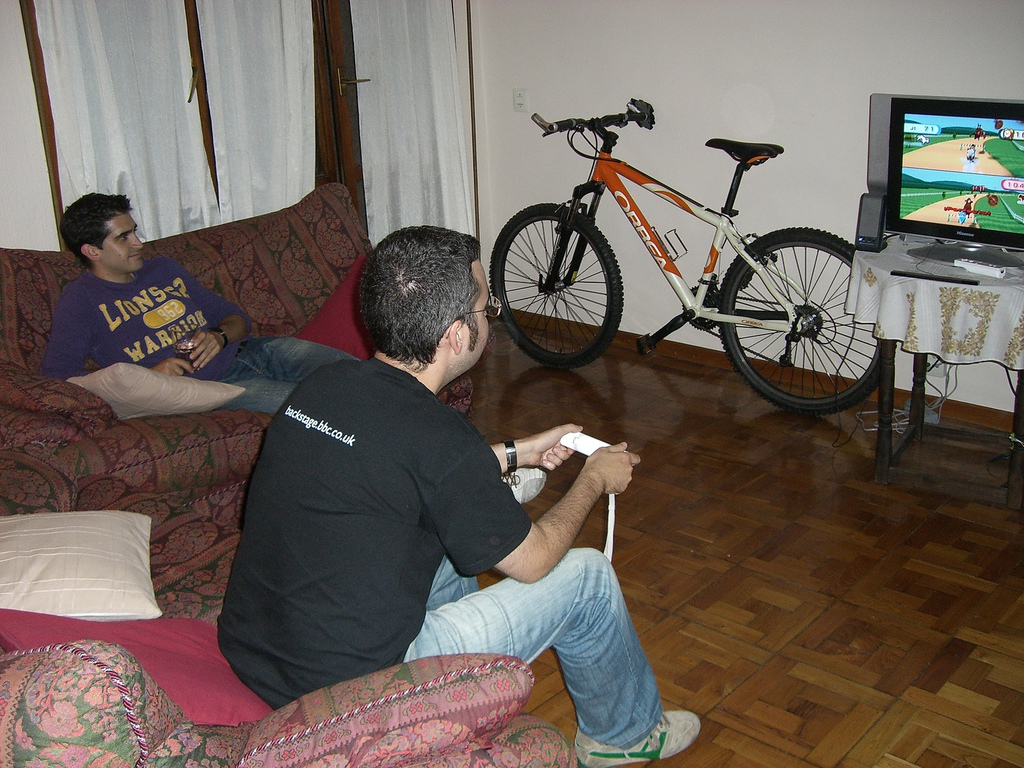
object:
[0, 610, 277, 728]
pillow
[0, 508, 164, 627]
pillow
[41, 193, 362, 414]
man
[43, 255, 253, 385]
blue shirt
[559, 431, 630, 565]
controller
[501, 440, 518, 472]
watch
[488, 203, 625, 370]
tire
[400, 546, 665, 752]
blue pants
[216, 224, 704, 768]
man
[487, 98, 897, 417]
bike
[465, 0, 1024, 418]
wall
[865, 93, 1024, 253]
tv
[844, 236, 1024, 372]
table cloth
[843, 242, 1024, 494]
table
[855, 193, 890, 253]
speaker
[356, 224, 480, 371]
black hair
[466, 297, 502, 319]
glasses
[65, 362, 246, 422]
pillow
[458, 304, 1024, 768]
floor